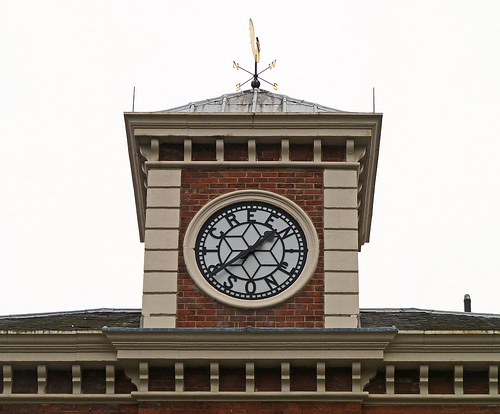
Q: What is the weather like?
A: It is cloudy.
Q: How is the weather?
A: It is cloudy.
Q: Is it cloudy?
A: Yes, it is cloudy.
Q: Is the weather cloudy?
A: Yes, it is cloudy.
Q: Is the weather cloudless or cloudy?
A: It is cloudy.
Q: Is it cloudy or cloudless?
A: It is cloudy.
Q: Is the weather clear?
A: No, it is cloudy.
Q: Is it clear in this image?
A: No, it is cloudy.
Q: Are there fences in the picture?
A: No, there are no fences.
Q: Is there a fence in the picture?
A: No, there are no fences.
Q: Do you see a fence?
A: No, there are no fences.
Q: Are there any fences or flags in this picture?
A: No, there are no fences or flags.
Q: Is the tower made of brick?
A: Yes, the tower is made of brick.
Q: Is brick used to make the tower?
A: Yes, the tower is made of brick.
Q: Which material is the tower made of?
A: The tower is made of brick.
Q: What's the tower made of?
A: The tower is made of brick.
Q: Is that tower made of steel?
A: No, the tower is made of brick.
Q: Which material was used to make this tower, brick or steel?
A: The tower is made of brick.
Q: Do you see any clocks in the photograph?
A: Yes, there is a clock.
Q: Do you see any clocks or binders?
A: Yes, there is a clock.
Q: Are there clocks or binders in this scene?
A: Yes, there is a clock.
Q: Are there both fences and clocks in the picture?
A: No, there is a clock but no fences.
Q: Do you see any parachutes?
A: No, there are no parachutes.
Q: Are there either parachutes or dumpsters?
A: No, there are no parachutes or dumpsters.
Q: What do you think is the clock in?
A: The clock is in the tower.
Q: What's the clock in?
A: The clock is in the tower.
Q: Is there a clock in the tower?
A: Yes, there is a clock in the tower.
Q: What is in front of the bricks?
A: The clock is in front of the bricks.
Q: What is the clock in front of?
A: The clock is in front of the bricks.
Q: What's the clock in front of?
A: The clock is in front of the bricks.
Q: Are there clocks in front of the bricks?
A: Yes, there is a clock in front of the bricks.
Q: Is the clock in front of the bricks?
A: Yes, the clock is in front of the bricks.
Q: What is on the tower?
A: The clock is on the tower.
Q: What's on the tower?
A: The clock is on the tower.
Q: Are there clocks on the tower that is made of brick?
A: Yes, there is a clock on the tower.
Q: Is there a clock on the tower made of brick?
A: Yes, there is a clock on the tower.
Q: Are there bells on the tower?
A: No, there is a clock on the tower.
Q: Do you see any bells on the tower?
A: No, there is a clock on the tower.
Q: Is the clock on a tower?
A: Yes, the clock is on a tower.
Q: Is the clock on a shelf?
A: No, the clock is on a tower.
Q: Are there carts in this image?
A: No, there are no carts.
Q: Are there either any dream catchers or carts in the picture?
A: No, there are no carts or dream catchers.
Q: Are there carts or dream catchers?
A: No, there are no carts or dream catchers.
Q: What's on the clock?
A: The letter is on the clock.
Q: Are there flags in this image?
A: No, there are no flags.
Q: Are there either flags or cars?
A: No, there are no flags or cars.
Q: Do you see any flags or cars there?
A: No, there are no flags or cars.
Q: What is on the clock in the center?
A: The letter is on the clock.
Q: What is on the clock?
A: The letter is on the clock.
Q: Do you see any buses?
A: No, there are no buses.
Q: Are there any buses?
A: No, there are no buses.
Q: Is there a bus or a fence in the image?
A: No, there are no buses or fences.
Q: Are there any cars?
A: No, there are no cars.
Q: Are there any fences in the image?
A: No, there are no fences.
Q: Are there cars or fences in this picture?
A: No, there are no fences or cars.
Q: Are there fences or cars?
A: No, there are no fences or cars.